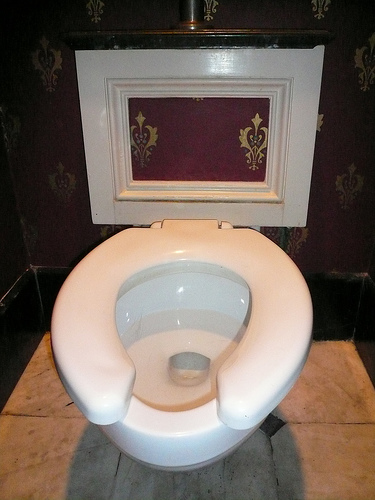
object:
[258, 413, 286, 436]
spot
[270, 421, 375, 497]
tile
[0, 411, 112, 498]
floor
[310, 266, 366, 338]
tile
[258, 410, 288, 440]
damage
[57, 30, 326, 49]
tank cover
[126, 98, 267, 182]
wallpaper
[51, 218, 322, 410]
toilet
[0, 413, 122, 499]
floor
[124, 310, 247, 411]
water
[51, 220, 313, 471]
toilet bowl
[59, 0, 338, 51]
blacklid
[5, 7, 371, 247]
wall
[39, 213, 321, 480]
toilet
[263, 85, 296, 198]
ground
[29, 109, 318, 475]
toilet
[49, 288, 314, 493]
seat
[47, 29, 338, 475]
toilet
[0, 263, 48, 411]
baseboards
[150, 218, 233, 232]
hinge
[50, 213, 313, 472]
toliet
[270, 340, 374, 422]
tile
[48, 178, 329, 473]
toilet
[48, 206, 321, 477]
white toilet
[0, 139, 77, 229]
shadow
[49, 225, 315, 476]
toilet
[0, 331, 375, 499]
ground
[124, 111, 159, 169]
design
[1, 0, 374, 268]
wallpaper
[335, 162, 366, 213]
design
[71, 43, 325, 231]
frame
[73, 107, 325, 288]
picture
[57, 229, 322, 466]
toilet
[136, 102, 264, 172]
wallpaper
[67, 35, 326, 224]
tank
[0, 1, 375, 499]
bathroom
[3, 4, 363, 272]
wall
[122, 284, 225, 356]
bowl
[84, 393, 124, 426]
light